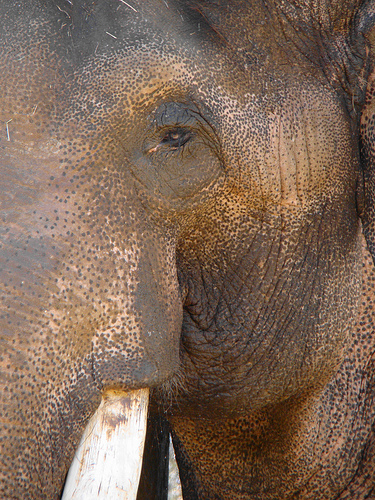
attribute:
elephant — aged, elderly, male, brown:
[1, 1, 375, 500]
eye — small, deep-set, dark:
[147, 122, 199, 150]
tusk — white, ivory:
[58, 385, 150, 500]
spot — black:
[49, 175, 56, 181]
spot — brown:
[100, 412, 128, 440]